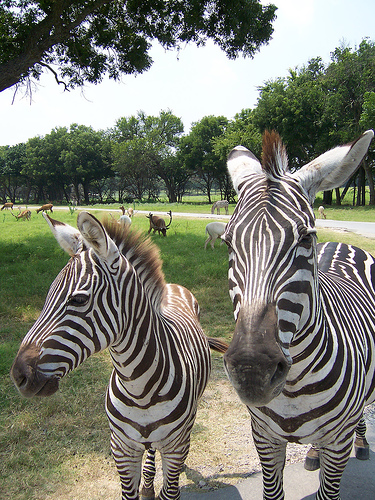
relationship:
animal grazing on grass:
[36, 203, 53, 213] [1, 183, 373, 497]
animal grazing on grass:
[10, 209, 31, 219] [1, 183, 373, 497]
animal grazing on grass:
[1, 202, 13, 210] [1, 183, 373, 497]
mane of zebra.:
[101, 216, 168, 297] [160, 135, 373, 435]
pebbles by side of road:
[183, 383, 311, 498] [311, 216, 373, 234]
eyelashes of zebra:
[67, 292, 90, 302] [13, 211, 214, 498]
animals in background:
[1, 201, 327, 245] [2, 1, 373, 221]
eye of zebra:
[69, 291, 92, 304] [13, 211, 214, 498]